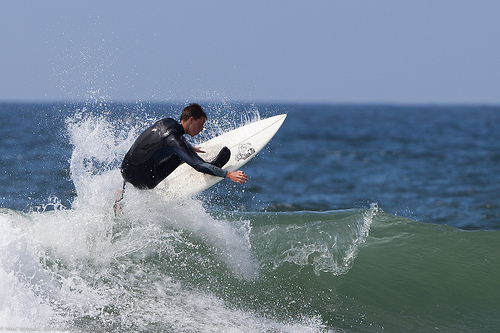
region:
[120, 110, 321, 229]
the surfboard is white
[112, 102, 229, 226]
the wet suit is black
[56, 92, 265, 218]
male surfer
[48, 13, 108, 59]
white clouds in blue sky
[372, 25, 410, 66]
white clouds in blue sky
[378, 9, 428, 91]
white clouds in blue sky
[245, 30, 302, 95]
white clouds in blue sky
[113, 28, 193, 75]
white clouds in blue sky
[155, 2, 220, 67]
white clouds in blue sky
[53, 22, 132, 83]
white clouds in blue sky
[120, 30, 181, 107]
white clouds in blue sky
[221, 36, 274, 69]
white clouds in blue sky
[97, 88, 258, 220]
man is on surfboard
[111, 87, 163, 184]
man has black wetsuit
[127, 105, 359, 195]
man on white board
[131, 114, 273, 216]
right arm is extended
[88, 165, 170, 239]
black cable on board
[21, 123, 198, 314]
man makes white wake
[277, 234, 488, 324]
clear and blue water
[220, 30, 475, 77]
sky is blue and clear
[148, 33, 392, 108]
few clouds in sky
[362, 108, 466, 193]
dark blue water in distance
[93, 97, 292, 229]
surfer riding high on wave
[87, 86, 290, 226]
surfer on top of ocean wave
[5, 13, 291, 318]
splash created by surf board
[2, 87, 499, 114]
distant horizon between ocean and sky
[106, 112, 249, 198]
men's wet black wetsuit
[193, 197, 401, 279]
cresting green tinted ocean wave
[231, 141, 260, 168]
logo on white surf board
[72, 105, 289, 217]
white surf board on water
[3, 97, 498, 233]
calm blue ocean water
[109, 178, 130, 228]
surf board attachment cord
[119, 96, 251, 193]
boy surfing on a white board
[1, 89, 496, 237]
deep nay blue ocean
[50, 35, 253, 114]
white water spray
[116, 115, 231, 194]
shiny black wet suit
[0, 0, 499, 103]
light blue clear sky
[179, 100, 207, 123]
short brown spiky hair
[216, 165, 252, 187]
boy's right hand extended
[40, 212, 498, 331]
grayish green coloured sea water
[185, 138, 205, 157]
boy's left hand clutching boar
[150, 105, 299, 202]
pointed white surf board